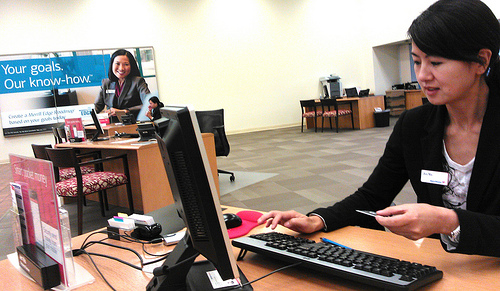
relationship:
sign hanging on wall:
[0, 47, 159, 136] [2, 1, 371, 158]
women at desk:
[88, 0, 496, 125] [0, 194, 495, 288]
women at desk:
[88, 0, 496, 125] [42, 108, 251, 257]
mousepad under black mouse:
[216, 192, 282, 256] [223, 213, 242, 229]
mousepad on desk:
[226, 210, 267, 240] [0, 194, 495, 288]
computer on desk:
[135, 105, 256, 291] [103, 249, 154, 277]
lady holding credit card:
[256, 0, 500, 258] [357, 208, 387, 218]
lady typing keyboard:
[256, 0, 500, 258] [224, 206, 463, 288]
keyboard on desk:
[233, 231, 444, 288] [0, 205, 499, 290]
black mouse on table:
[218, 205, 254, 225] [361, 226, 438, 256]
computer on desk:
[135, 105, 256, 291] [0, 205, 499, 290]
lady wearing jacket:
[361, 13, 489, 213] [368, 116, 488, 206]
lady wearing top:
[256, 0, 500, 258] [424, 129, 486, 251]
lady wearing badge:
[256, 0, 500, 258] [412, 155, 449, 188]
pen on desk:
[319, 235, 351, 249] [0, 205, 499, 290]